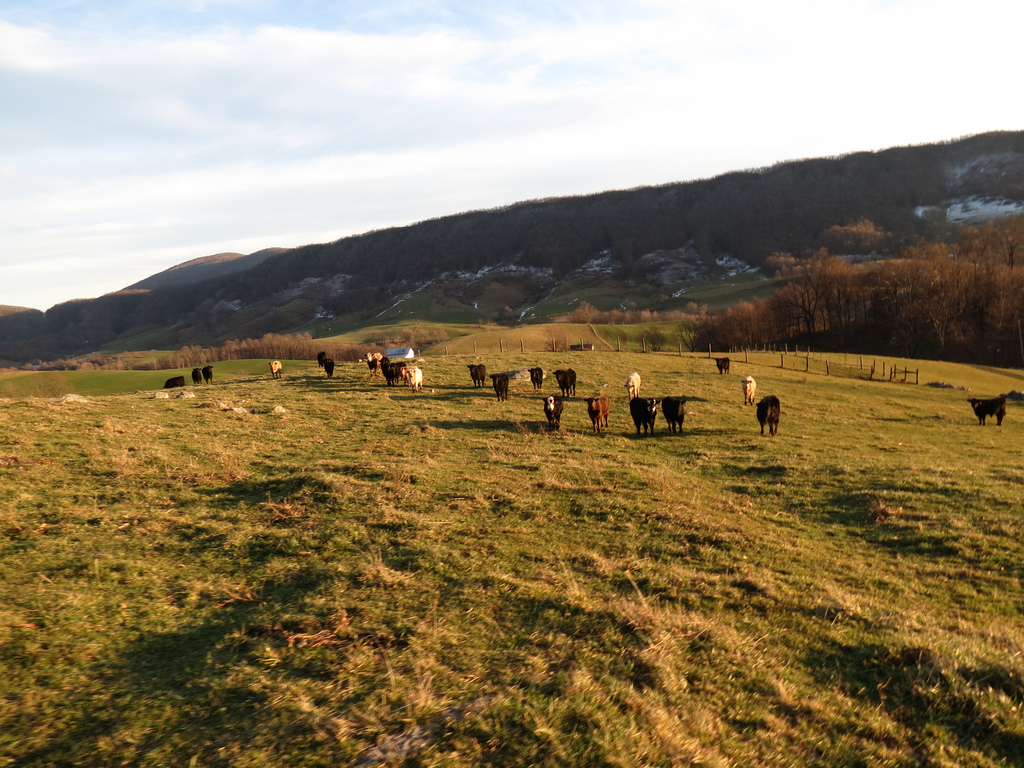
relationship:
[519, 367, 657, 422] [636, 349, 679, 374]
cows on top of hillside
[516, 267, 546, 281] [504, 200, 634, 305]
snow on top of hill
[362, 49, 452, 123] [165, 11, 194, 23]
clouds in sky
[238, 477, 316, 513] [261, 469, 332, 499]
shadows on top of grass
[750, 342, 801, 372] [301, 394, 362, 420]
fence on top of pasture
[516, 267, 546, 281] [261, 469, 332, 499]
snow on top of grass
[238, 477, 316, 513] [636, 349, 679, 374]
shadows on top of hillside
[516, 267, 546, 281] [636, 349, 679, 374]
snow on top of hillside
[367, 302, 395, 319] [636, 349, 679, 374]
ravine attached to hillside